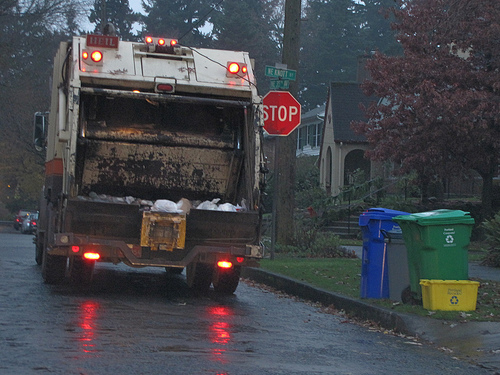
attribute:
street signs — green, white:
[268, 62, 295, 91]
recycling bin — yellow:
[416, 279, 480, 315]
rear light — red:
[214, 257, 234, 271]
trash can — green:
[394, 206, 474, 302]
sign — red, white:
[260, 85, 303, 139]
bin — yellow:
[416, 276, 482, 313]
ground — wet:
[12, 284, 418, 373]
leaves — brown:
[308, 299, 348, 321]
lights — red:
[79, 48, 265, 80]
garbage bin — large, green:
[392, 207, 472, 299]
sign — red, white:
[260, 90, 303, 140]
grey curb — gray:
[236, 261, 454, 372]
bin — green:
[394, 186, 483, 291]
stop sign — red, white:
[260, 79, 309, 157]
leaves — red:
[400, 50, 497, 172]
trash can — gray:
[386, 228, 413, 296]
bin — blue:
[360, 206, 405, 294]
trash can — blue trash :
[354, 202, 409, 297]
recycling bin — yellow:
[420, 278, 479, 310]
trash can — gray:
[384, 223, 417, 309]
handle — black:
[378, 226, 395, 243]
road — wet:
[6, 284, 386, 371]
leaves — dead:
[362, 52, 482, 168]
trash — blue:
[350, 202, 387, 293]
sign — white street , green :
[265, 62, 300, 84]